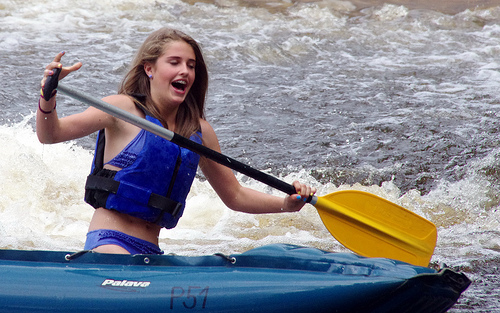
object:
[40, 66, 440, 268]
paddle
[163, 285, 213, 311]
writing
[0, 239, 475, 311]
boat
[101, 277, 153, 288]
writing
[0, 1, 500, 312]
water